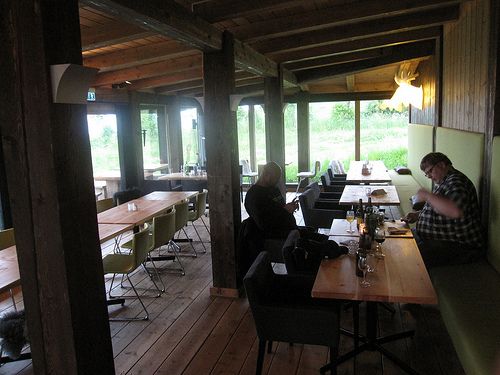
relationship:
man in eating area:
[410, 151, 485, 267] [0, 2, 500, 372]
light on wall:
[387, 73, 425, 111] [408, 4, 499, 134]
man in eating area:
[244, 160, 300, 238] [0, 2, 500, 372]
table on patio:
[97, 188, 200, 223] [0, 190, 456, 375]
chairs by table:
[153, 187, 211, 276] [97, 188, 200, 223]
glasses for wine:
[347, 206, 387, 289] [357, 197, 374, 226]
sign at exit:
[84, 88, 97, 102] [86, 105, 124, 197]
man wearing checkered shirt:
[410, 151, 485, 267] [415, 169, 486, 247]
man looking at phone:
[244, 160, 300, 238] [288, 196, 299, 206]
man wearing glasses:
[410, 151, 485, 267] [424, 167, 437, 176]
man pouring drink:
[410, 151, 485, 267] [407, 197, 425, 228]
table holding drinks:
[309, 217, 440, 306] [347, 206, 387, 289]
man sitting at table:
[410, 151, 485, 267] [327, 217, 414, 238]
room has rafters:
[0, 2, 500, 372] [78, 0, 461, 101]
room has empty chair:
[0, 2, 500, 372] [102, 230, 161, 321]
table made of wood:
[159, 171, 216, 184] [159, 171, 205, 180]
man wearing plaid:
[410, 151, 485, 267] [415, 169, 486, 247]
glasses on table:
[347, 206, 387, 289] [309, 217, 440, 306]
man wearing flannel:
[410, 151, 485, 267] [415, 169, 486, 247]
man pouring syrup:
[410, 151, 485, 267] [409, 196, 426, 210]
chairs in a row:
[153, 187, 211, 276] [122, 187, 212, 292]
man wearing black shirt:
[244, 160, 300, 238] [244, 185, 297, 237]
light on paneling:
[387, 73, 425, 111] [410, 57, 438, 125]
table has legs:
[309, 217, 440, 306] [320, 299, 420, 375]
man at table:
[410, 151, 485, 267] [327, 217, 414, 238]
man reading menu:
[244, 160, 300, 238] [285, 196, 300, 214]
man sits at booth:
[410, 151, 485, 267] [387, 123, 499, 374]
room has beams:
[102, 230, 161, 321] [81, 1, 296, 87]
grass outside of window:
[359, 148, 410, 170] [357, 101, 410, 176]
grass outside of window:
[309, 159, 331, 187] [308, 100, 356, 180]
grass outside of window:
[284, 159, 299, 184] [253, 102, 298, 183]